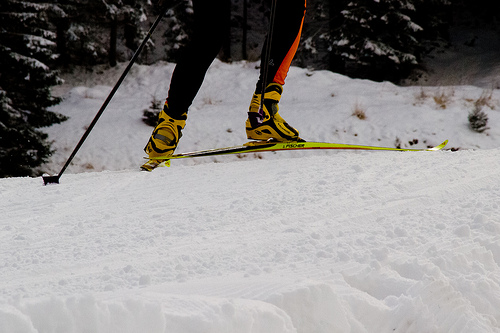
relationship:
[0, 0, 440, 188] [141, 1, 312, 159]
pine tree behind man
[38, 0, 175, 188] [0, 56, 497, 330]
pole sticking in snow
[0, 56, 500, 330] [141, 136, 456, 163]
snow below ski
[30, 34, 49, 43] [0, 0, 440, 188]
snow on pine tree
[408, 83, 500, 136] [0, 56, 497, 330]
dead grass on snow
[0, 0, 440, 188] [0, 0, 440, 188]
pine tree on pine tree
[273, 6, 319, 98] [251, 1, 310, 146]
stripe running down leg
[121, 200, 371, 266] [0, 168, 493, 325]
ground covered in snow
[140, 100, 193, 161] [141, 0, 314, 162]
shoe on man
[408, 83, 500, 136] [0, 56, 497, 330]
dead grass in snow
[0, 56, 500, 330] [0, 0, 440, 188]
snow on pine tree